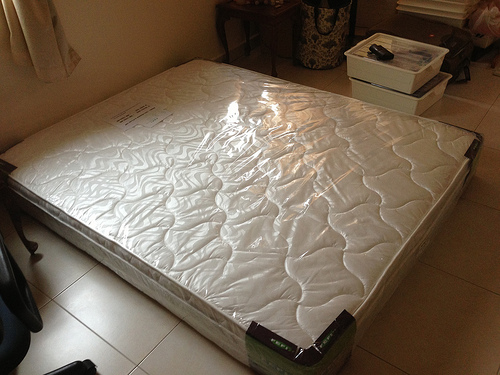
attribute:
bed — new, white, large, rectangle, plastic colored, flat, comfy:
[2, 56, 485, 374]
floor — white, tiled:
[3, 12, 497, 373]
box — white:
[345, 70, 452, 115]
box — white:
[343, 28, 451, 96]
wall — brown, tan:
[0, 1, 256, 154]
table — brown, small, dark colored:
[210, 0, 306, 80]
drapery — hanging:
[1, 0, 85, 83]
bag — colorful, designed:
[296, 2, 357, 72]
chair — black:
[0, 238, 97, 374]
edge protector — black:
[247, 308, 357, 375]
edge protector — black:
[437, 117, 487, 165]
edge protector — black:
[175, 54, 222, 68]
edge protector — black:
[2, 135, 32, 182]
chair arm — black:
[0, 237, 42, 335]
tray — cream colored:
[395, 1, 479, 27]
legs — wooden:
[210, 15, 303, 77]